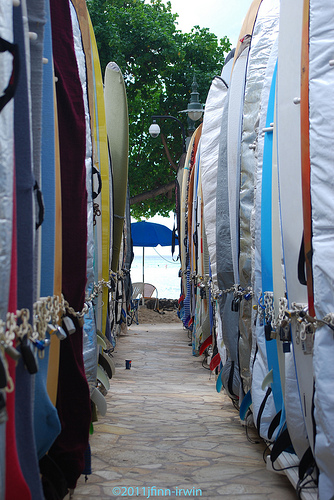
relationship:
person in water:
[161, 262, 170, 269] [131, 255, 180, 299]